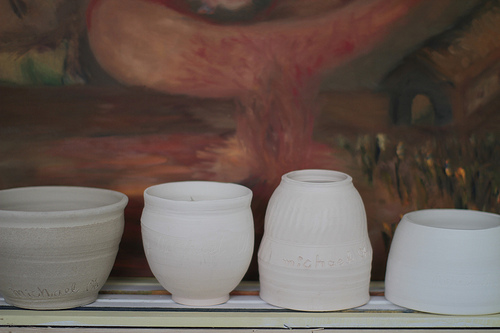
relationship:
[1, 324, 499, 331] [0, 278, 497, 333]
stripe on fixture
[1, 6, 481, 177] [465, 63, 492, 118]
painting on window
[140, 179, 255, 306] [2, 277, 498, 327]
bowls on fixture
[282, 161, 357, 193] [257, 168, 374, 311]
bottom of bowls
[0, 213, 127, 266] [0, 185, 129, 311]
ribbed circles on beige bowl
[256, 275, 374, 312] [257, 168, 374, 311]
base of bowls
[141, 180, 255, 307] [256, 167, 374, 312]
bowls beside vase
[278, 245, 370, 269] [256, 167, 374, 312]
name carved into vase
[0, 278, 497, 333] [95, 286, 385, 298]
fixture with stripe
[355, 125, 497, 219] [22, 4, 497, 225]
vegetation in painting